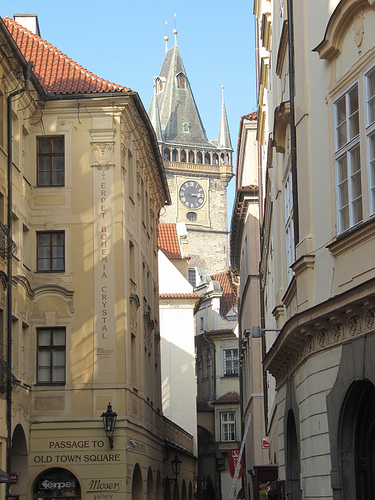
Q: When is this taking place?
A: Daytime.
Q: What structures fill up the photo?
A: Buildings.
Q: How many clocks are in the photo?
A: One.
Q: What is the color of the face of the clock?
A: Black and white.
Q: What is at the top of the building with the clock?
A: Steeple.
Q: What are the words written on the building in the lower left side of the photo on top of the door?
A: Passage to old town square.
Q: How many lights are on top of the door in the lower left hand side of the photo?
A: One.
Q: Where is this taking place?
A: London.